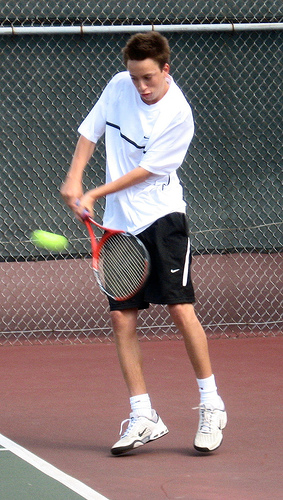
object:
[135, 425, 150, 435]
check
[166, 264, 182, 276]
check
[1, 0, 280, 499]
court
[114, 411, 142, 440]
laces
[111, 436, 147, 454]
edge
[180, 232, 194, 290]
line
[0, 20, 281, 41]
pole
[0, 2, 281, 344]
fence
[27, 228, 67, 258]
ball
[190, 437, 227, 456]
trim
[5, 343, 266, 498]
tennis court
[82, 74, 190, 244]
shirt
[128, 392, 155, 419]
sock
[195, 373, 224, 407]
sock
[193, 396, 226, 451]
sneakers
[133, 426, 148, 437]
mark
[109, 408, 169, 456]
shoe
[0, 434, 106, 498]
line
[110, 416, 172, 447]
side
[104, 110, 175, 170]
stripe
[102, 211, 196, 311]
shorts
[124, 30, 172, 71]
hair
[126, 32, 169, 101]
head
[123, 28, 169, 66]
spikey hair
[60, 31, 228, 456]
boy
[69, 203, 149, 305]
racket